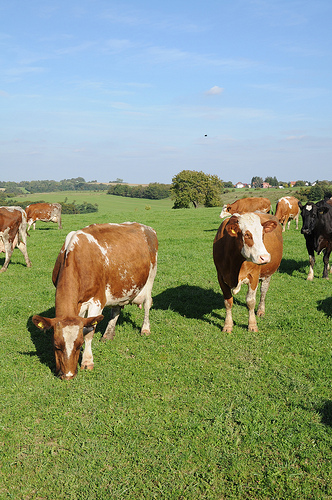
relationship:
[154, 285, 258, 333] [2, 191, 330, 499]
shadow appears on ground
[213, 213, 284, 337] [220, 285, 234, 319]
cow has a leg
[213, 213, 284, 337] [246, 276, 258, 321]
cow has a leg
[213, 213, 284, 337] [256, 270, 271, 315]
cow has a leg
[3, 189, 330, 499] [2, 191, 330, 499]
grass on ground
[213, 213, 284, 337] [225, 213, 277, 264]
cow has a head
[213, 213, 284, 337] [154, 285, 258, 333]
cow casting a shadow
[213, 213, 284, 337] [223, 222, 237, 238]
cow has an ear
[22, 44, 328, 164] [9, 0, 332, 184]
clouds are in sky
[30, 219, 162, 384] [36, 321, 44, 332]
cow has a tag